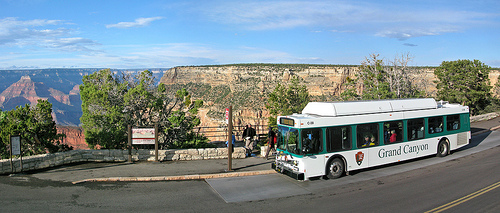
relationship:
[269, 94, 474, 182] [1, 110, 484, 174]
bus parked in front of wall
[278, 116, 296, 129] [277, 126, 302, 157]
destination window mounted above window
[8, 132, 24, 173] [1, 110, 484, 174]
sign standing in front of wall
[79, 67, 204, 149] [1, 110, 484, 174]
tree visible behind wall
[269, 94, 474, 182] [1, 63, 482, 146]
bus parked in front of grand canyon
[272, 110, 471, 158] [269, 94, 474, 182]
trim painted on bus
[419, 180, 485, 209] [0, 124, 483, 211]
double line painted on road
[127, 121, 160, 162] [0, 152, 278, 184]
sign on sidewalk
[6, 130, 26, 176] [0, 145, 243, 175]
sign by wall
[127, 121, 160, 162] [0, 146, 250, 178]
sign by wall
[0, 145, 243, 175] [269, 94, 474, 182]
wall behind bus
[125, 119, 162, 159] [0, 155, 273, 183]
sign on sidewalk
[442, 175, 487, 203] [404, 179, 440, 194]
lines on street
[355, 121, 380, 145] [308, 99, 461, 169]
window on bus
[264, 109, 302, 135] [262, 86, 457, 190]
window on bus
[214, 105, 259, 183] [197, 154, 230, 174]
pole on sidewalk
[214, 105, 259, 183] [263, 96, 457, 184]
pole in front of bus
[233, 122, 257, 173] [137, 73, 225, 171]
man looking over grand canyon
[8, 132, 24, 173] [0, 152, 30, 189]
sign on poles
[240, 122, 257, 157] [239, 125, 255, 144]
man in jacket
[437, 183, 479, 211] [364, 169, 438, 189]
lines on road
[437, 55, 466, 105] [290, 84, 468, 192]
tree behind bus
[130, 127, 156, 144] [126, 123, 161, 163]
sign held by poles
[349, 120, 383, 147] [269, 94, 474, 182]
window on bus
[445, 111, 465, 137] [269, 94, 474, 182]
window on bus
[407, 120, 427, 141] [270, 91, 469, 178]
window on bus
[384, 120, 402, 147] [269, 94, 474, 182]
window on bus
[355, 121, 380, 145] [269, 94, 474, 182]
window on bus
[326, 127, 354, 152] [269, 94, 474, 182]
window on bus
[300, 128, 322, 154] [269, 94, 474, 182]
window on bus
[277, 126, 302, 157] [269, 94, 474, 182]
window on bus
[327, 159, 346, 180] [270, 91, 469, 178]
wheel on bus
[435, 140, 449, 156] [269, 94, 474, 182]
wheel on bus